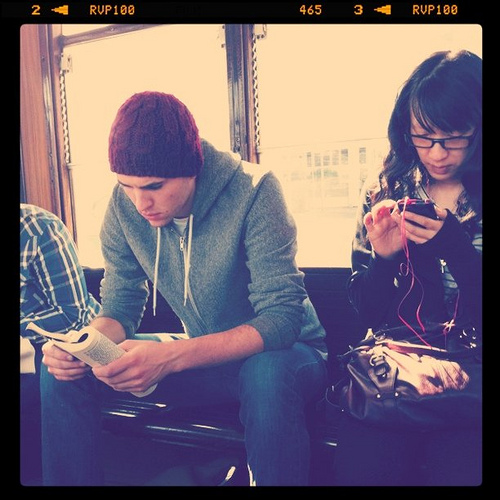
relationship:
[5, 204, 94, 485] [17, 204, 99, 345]
passenger wearing a shirt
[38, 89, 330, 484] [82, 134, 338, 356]
man wearing a hoodie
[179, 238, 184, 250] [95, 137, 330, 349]
zipper on shirt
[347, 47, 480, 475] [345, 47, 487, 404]
shirt on girl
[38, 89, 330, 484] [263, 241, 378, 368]
man has bench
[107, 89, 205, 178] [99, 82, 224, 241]
hat on head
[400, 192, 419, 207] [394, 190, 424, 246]
headphone plugged into phone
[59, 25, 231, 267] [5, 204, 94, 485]
window behind passenger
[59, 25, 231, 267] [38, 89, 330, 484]
window behind man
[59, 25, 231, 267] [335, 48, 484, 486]
window behind person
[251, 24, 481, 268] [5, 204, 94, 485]
window behind passenger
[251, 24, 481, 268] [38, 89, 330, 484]
window behind man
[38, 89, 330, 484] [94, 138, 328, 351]
man wearing a hoodie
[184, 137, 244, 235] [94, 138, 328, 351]
hood on a hoodie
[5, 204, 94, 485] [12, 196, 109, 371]
passenger wearing shirt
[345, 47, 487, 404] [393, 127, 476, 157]
girl wearing glasses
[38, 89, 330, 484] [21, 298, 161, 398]
man reading book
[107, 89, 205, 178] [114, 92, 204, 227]
hat on head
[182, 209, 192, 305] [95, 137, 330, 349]
string on shirt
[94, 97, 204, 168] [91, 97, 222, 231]
hat on head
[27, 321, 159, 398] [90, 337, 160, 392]
book in h hand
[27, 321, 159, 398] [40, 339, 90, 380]
book in h hand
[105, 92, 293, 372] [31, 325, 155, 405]
guy reading a book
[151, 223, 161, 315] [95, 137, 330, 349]
string coming from shirt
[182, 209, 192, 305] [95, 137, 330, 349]
string coming from shirt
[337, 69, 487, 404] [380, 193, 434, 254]
girl on a phone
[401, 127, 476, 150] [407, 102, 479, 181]
glasses on her face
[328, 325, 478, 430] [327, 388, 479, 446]
purse on her lap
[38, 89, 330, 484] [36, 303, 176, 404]
man reading a book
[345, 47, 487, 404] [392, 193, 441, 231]
girl scrolling on her smartphone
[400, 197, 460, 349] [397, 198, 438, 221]
earbud cord plugged in cellphone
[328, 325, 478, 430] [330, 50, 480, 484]
purse beside woman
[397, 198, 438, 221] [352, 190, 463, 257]
cellphone in womans hands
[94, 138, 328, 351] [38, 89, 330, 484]
hoodie worn by young man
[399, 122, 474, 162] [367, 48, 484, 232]
glasses on woman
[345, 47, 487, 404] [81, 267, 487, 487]
girl sitting on bench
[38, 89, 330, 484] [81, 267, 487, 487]
man sitting on bench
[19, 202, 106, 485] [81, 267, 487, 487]
passenger sitting on bench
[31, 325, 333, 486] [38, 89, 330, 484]
jeans worn by man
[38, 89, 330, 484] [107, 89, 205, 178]
man wearing hat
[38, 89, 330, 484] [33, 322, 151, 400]
man holding book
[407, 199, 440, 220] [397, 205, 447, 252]
cellphone inside of hand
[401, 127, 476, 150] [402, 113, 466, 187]
glasses sitting on face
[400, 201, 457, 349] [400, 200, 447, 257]
earbud cord hanging from phone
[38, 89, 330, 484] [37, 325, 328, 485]
man wearing jeans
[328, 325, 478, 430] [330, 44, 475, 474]
purse sitting on woman's lap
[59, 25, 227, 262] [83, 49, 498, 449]
window behind people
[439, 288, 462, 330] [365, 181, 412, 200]
string hanging from shirt